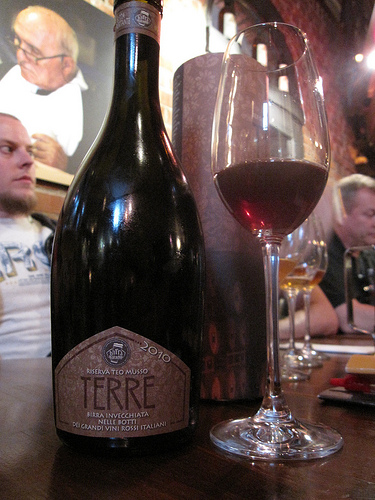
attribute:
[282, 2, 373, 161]
wall — brick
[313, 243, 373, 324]
shirt — black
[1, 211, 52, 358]
shirt — white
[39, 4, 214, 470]
bottle — black, wine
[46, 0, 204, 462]
bottle — black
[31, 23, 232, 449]
bottle — black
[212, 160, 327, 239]
wine — purple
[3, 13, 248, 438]
bottle — black, wine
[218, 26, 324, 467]
wine — black, bottle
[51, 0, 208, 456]
black bottle — wine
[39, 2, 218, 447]
wine bottle — black